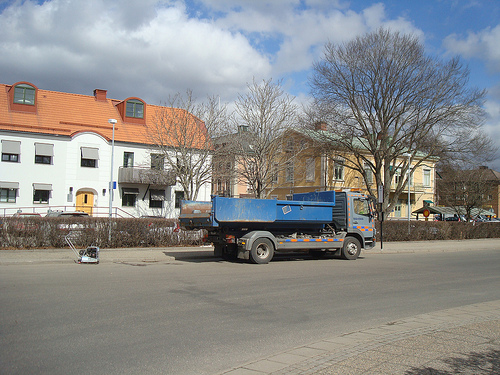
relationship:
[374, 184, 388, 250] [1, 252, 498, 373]
sign on road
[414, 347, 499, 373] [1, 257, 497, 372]
shadow on sidewalk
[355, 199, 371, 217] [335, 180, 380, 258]
front window of cab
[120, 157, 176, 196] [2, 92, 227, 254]
balcony of apartment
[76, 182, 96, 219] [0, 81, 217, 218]
yellow of apartment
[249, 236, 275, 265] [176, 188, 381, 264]
tire of dumptruck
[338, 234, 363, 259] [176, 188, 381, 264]
tire of dumptruck